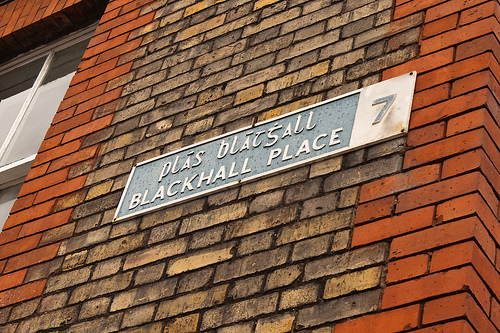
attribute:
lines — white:
[5, 30, 76, 260]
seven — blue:
[368, 92, 398, 124]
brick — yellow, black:
[124, 240, 191, 270]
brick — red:
[345, 196, 442, 251]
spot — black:
[383, 109, 405, 139]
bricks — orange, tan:
[269, 212, 456, 332]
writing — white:
[124, 104, 354, 214]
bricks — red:
[349, 176, 499, 281]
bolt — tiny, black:
[409, 70, 414, 73]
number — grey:
[357, 89, 398, 128]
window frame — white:
[7, 34, 67, 141]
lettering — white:
[129, 110, 343, 210]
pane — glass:
[12, 37, 106, 183]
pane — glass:
[3, 50, 51, 165]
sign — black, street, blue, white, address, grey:
[111, 71, 418, 224]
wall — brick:
[2, 0, 498, 332]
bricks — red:
[11, 0, 460, 323]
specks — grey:
[327, 100, 352, 122]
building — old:
[46, 87, 405, 326]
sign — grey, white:
[119, 70, 434, 215]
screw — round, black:
[400, 65, 416, 79]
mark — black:
[382, 105, 408, 133]